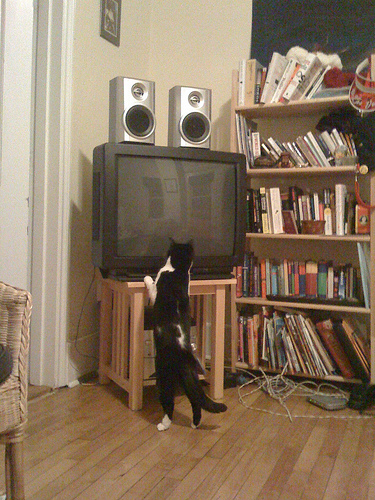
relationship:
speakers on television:
[168, 85, 211, 150] [90, 142, 246, 281]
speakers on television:
[108, 76, 156, 144] [90, 142, 246, 281]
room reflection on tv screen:
[119, 156, 234, 249] [116, 153, 238, 253]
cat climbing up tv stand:
[142, 234, 227, 431] [187, 273, 238, 381]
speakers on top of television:
[108, 76, 156, 144] [90, 142, 246, 281]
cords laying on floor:
[233, 356, 357, 433] [119, 431, 332, 477]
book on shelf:
[304, 260, 317, 299] [236, 295, 370, 313]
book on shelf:
[317, 259, 330, 301] [236, 295, 370, 313]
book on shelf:
[259, 259, 265, 298] [236, 295, 370, 313]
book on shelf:
[271, 263, 278, 298] [236, 295, 370, 313]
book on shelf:
[339, 263, 344, 299] [236, 295, 370, 313]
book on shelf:
[242, 260, 360, 300] [234, 295, 369, 315]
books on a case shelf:
[245, 254, 361, 300] [224, 61, 374, 392]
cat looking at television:
[142, 234, 227, 431] [90, 142, 246, 281]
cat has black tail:
[142, 234, 227, 431] [176, 368, 217, 413]